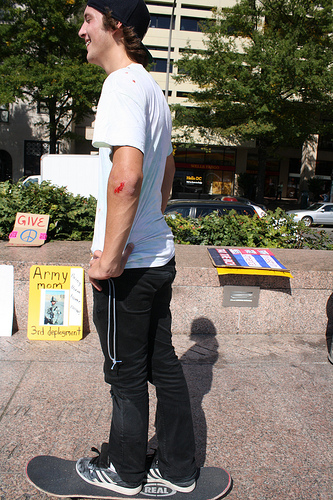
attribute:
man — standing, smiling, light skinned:
[77, 0, 200, 494]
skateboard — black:
[25, 454, 232, 500]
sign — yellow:
[25, 263, 87, 342]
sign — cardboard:
[5, 212, 50, 249]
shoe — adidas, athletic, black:
[145, 447, 197, 492]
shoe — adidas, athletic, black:
[75, 440, 144, 497]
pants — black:
[91, 255, 200, 488]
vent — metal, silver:
[219, 283, 262, 308]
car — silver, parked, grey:
[283, 199, 332, 230]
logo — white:
[139, 482, 177, 498]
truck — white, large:
[16, 151, 100, 210]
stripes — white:
[88, 466, 117, 486]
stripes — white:
[145, 462, 161, 483]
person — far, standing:
[272, 179, 285, 203]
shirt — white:
[88, 62, 176, 268]